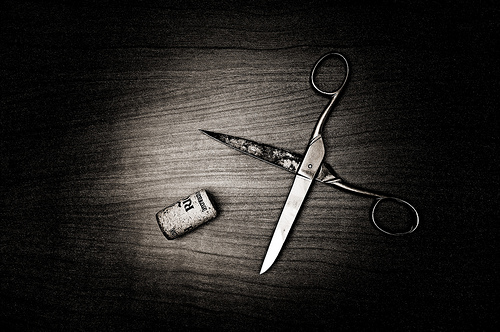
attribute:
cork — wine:
[152, 179, 225, 239]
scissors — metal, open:
[199, 50, 421, 277]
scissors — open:
[183, 40, 429, 280]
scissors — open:
[179, 22, 432, 282]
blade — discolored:
[196, 121, 291, 175]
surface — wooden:
[1, 2, 497, 327]